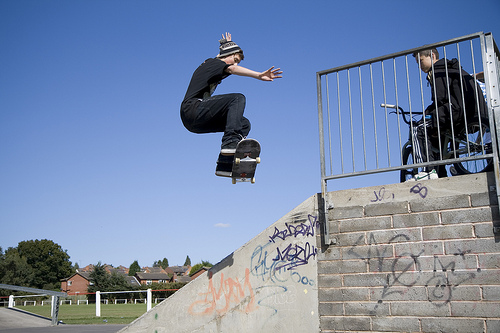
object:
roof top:
[60, 271, 93, 281]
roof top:
[169, 265, 188, 272]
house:
[61, 263, 211, 300]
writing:
[347, 233, 475, 314]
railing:
[316, 30, 500, 181]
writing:
[188, 214, 317, 316]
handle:
[380, 103, 396, 108]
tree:
[0, 238, 73, 301]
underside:
[232, 140, 261, 177]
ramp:
[117, 192, 322, 333]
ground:
[0, 304, 145, 332]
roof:
[136, 272, 170, 279]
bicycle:
[379, 104, 500, 183]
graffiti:
[191, 185, 476, 316]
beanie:
[219, 32, 243, 58]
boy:
[403, 48, 470, 184]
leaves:
[28, 241, 54, 266]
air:
[7, 0, 498, 301]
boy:
[180, 43, 283, 177]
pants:
[180, 93, 251, 163]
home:
[61, 265, 208, 303]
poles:
[315, 31, 500, 245]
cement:
[119, 192, 318, 333]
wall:
[118, 173, 500, 333]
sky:
[0, 0, 500, 270]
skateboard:
[232, 138, 261, 178]